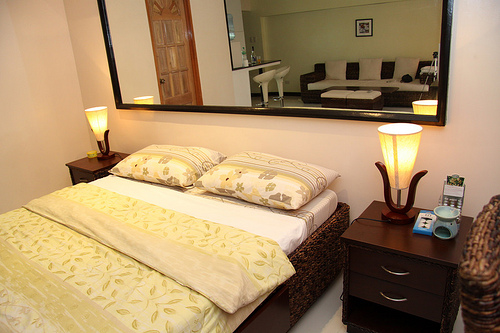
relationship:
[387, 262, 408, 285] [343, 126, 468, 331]
handles on drawers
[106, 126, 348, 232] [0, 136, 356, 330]
pillows on bed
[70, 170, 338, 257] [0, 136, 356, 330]
bedspread on bed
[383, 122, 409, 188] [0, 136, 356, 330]
lamp near bed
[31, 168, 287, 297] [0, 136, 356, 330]
bedspread on bed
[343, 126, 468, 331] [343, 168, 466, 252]
drawers under table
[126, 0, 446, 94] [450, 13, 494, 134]
mirror on wall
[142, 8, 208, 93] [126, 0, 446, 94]
door in mirror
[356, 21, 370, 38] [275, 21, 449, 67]
photo reflected on wall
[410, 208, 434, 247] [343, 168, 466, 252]
box on table